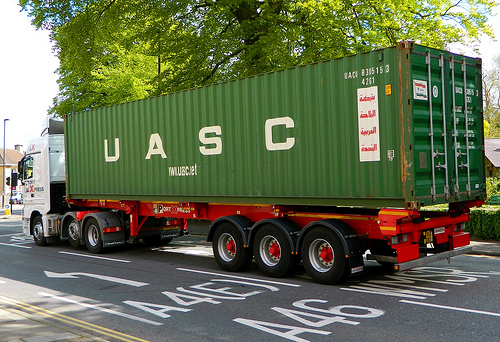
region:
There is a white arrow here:
[41, 263, 88, 323]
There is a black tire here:
[263, 235, 282, 288]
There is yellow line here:
[41, 313, 74, 323]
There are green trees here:
[91, 41, 130, 78]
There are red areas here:
[385, 212, 406, 277]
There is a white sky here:
[15, 50, 33, 89]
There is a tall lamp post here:
[1, 118, 20, 173]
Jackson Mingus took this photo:
[111, 59, 214, 331]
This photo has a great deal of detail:
[134, 66, 203, 271]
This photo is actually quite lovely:
[88, 68, 219, 332]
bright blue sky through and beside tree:
[10, 0, 496, 147]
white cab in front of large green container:
[20, 40, 485, 276]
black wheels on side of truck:
[60, 192, 366, 282]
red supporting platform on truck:
[67, 196, 468, 266]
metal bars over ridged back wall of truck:
[405, 41, 485, 201]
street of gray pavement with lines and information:
[5, 225, 496, 335]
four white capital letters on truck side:
[100, 110, 297, 161]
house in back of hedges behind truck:
[480, 52, 495, 244]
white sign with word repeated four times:
[355, 80, 380, 165]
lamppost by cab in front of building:
[1, 112, 32, 233]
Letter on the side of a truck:
[103, 135, 121, 164]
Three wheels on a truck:
[204, 215, 351, 284]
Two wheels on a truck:
[58, 210, 123, 252]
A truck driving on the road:
[17, 40, 482, 283]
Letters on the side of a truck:
[101, 113, 299, 178]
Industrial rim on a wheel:
[68, 218, 80, 239]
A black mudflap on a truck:
[345, 243, 367, 276]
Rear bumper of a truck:
[393, 244, 478, 271]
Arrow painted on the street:
[43, 261, 151, 291]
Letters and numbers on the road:
[123, 276, 383, 338]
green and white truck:
[40, 100, 447, 227]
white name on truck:
[76, 115, 311, 192]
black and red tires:
[215, 224, 373, 286]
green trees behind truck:
[62, 10, 451, 104]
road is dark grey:
[80, 287, 158, 315]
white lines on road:
[65, 253, 282, 338]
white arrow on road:
[32, 265, 152, 292]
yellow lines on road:
[1, 273, 115, 332]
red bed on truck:
[72, 188, 432, 268]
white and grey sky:
[0, 32, 52, 137]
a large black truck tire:
[297, 224, 346, 277]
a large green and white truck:
[11, 42, 484, 287]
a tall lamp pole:
[0, 118, 15, 209]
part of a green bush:
[472, 207, 499, 240]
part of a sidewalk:
[469, 235, 499, 252]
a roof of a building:
[1, 146, 24, 161]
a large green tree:
[47, 3, 182, 100]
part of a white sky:
[5, 34, 52, 91]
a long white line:
[400, 297, 498, 320]